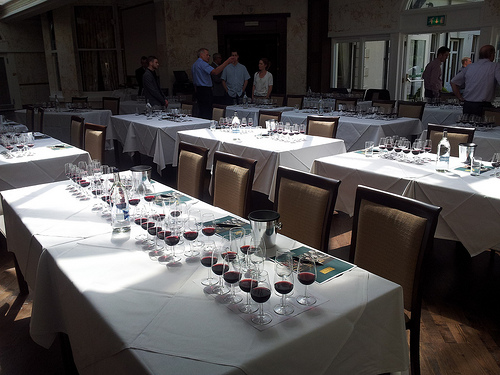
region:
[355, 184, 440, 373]
part of a brown chair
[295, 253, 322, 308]
a glass of wine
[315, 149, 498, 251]
part of a white tablecloth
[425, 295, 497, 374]
a section of brown hardwood floor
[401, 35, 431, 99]
a white door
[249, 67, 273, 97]
a woman's white shirt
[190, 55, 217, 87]
a man's blue shirt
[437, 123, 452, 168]
a tall bottle of wine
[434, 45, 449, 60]
a man's short cut hair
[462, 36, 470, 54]
part of a painted white wall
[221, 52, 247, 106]
Man in a light blue shirt.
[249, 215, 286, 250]
The silver container.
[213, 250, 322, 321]
An array of glasses with wine.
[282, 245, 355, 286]
The placemat on the table.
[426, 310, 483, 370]
Part of the wooden floor.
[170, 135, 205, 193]
Chair at the table.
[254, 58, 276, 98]
Woman in a white shirt standing.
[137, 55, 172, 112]
Man in a black shirt standing.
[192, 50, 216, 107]
Man in a blue shirt standing.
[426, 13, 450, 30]
Green sign above the door.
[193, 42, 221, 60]
head of a person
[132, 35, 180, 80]
head of a person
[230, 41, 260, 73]
head of a person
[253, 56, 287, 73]
head of a person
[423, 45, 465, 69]
head of a person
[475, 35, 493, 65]
head of a person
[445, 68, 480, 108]
arm of a person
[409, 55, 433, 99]
arm of a person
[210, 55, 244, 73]
arm of a person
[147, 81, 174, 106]
arm of a person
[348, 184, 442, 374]
A brown hard backed chair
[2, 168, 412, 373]
A table covered in a white cloth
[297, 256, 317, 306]
A glass of red wine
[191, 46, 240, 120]
A man with his arm extended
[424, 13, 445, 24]
An exit sign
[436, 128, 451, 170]
A glass bottle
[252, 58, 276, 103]
A woman in a white shirt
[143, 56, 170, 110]
A man in a suit jacket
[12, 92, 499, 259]
A row of tables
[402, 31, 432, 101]
An open door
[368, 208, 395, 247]
first empty chair at table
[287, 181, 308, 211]
second empty chair at table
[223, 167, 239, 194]
third empty chair at table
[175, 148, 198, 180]
fourth empty chair at table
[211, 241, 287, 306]
first set of wine glasses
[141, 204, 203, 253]
second set of wine glasses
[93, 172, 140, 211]
third set of wine glasses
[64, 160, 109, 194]
fourth set of wine glasses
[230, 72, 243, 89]
man wearing blue shirt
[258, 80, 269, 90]
woman wearing white shirt